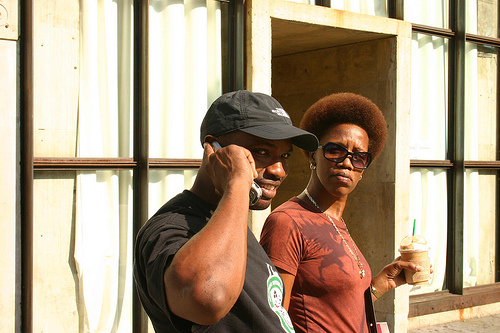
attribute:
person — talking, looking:
[131, 91, 299, 333]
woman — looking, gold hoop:
[280, 86, 440, 333]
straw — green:
[409, 217, 423, 243]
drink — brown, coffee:
[399, 242, 430, 286]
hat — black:
[199, 92, 318, 152]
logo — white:
[266, 107, 295, 120]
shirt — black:
[124, 194, 297, 333]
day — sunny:
[2, 2, 495, 332]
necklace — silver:
[305, 188, 368, 280]